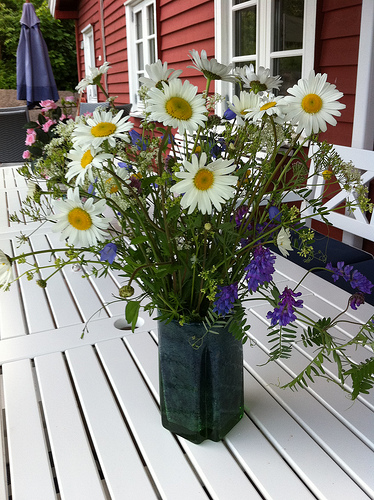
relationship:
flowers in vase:
[135, 60, 208, 136] [156, 302, 245, 445]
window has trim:
[138, 35, 150, 91] [126, 34, 160, 112]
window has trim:
[230, 36, 301, 93] [211, 34, 317, 146]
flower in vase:
[280, 67, 348, 138] [156, 302, 245, 445]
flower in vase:
[142, 75, 211, 134] [156, 302, 245, 445]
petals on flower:
[254, 274, 263, 279] [237, 236, 279, 292]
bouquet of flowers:
[11, 31, 350, 456] [141, 66, 231, 240]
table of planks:
[9, 147, 356, 477] [11, 363, 138, 497]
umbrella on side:
[7, 2, 68, 126] [8, 4, 83, 233]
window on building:
[122, 2, 159, 106] [67, 4, 358, 158]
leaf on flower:
[274, 323, 293, 356] [271, 289, 296, 371]